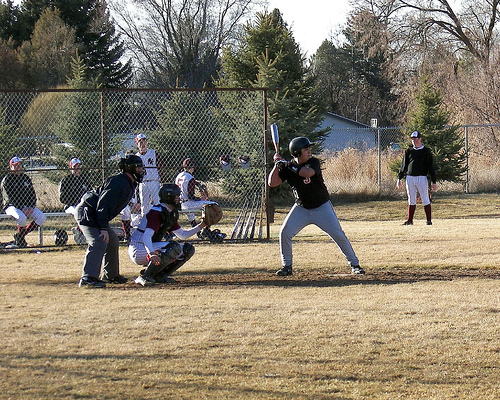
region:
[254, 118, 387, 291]
baseball player holding bat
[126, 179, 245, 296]
catcher with mit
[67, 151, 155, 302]
umpire with helmet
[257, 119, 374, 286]
baseball player with helmet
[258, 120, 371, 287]
baseball player getting ready for pitch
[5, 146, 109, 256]
two people on bench watching baseball game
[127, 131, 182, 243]
baseball player with hat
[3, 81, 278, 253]
metal fence behind home base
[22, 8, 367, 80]
trees and cloudy sky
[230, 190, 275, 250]
five bats leaning on metal fence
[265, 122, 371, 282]
Batter concentrating on pitch.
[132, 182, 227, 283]
Catcher concentrating on pitch.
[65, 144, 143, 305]
Umpire awaiting the pitch.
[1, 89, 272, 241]
Chain link fence covering dugout.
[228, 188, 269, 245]
Spare baseball bats for other players.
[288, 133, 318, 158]
Baseball batter's helmet for protection.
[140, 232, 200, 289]
Shin guards for protection against low pitches.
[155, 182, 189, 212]
Cather's mask for head protection.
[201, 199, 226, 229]
Thick cather's glove for protection against hard pitches.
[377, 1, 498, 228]
Long sleeved uniform for keeping warm.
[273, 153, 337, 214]
the batter is wearing a shirt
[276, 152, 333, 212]
the shirt is black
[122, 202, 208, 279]
the catcher is wearing a uniform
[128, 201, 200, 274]
the uniform is white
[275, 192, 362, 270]
the batter is wearing pants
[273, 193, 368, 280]
the pants are grey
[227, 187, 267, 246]
the bats are leaning against the fence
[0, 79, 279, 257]
the fence is behind the bater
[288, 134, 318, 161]
the batter is wearing a helmet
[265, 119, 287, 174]
the helmet is black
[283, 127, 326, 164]
the batter has a helmet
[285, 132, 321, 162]
the helmet is black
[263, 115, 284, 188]
the batter is holding a bat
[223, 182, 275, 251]
the bats are leaning on the fence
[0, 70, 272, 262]
the fence is behind the batter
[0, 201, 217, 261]
the players are sitting on the bench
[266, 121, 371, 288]
A man ready to swing a baseball bat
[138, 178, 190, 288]
an umpire holding up a baseball glove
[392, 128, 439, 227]
a baseball player standing on the sidelines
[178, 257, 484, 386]
a dry, brown grassy baseball field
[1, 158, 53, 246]
a baseball player sitting on a bench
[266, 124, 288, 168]
a baseball bat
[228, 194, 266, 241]
a row of baseball bats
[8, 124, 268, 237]
a chain link fence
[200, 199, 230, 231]
a baseball glove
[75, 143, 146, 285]
a baseball referee standing behind the umpire